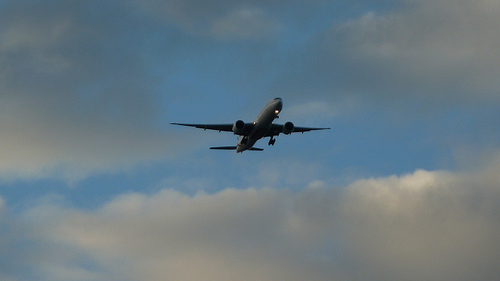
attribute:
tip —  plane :
[269, 99, 283, 121]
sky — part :
[0, 0, 497, 279]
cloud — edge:
[44, 193, 499, 277]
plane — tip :
[165, 94, 334, 155]